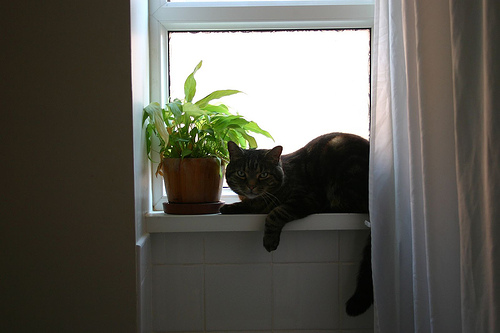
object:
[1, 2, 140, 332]
wall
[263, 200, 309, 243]
leg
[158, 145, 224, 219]
pot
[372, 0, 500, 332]
curtain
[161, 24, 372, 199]
window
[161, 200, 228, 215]
saucer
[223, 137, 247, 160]
ears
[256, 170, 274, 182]
eye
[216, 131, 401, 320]
cat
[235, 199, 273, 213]
leg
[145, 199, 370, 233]
sill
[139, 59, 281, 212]
houseplant